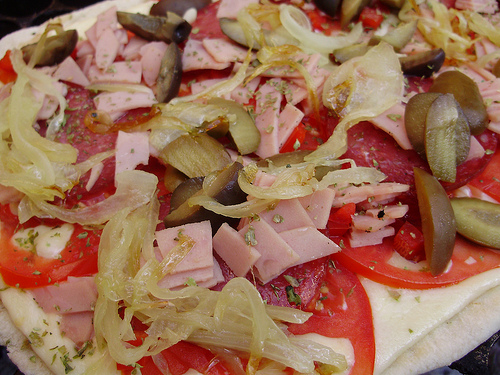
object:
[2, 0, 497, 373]
panini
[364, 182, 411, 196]
meat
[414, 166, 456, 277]
artichoke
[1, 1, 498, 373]
food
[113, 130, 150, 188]
meat piece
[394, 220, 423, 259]
red peppers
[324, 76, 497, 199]
red peppers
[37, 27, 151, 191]
red peppers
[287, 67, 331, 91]
meat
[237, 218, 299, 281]
meat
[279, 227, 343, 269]
meat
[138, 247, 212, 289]
meat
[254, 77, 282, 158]
meat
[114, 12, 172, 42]
mushrooms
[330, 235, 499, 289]
tomatoes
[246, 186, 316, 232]
meat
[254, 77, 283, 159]
dog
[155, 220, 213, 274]
meat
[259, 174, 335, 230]
meat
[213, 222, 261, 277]
meat